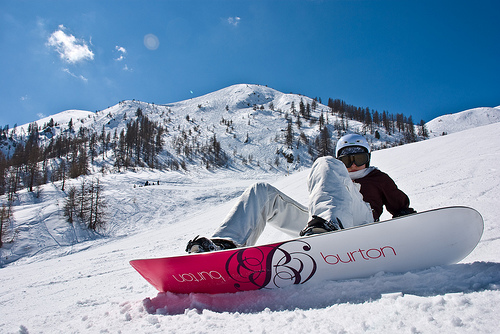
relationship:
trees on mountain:
[319, 97, 428, 140] [4, 78, 484, 242]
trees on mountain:
[100, 101, 170, 167] [4, 78, 484, 242]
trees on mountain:
[7, 126, 91, 183] [4, 78, 484, 242]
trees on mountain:
[55, 179, 108, 229] [4, 78, 484, 242]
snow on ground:
[17, 252, 118, 322] [9, 167, 498, 329]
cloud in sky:
[32, 20, 129, 92] [0, 3, 487, 138]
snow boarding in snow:
[128, 205, 486, 294] [0, 78, 500, 332]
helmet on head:
[333, 132, 372, 179] [339, 132, 372, 179]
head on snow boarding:
[339, 132, 372, 179] [128, 205, 486, 294]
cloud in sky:
[35, 24, 114, 82] [0, 3, 487, 138]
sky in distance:
[0, 3, 487, 138] [21, 12, 454, 125]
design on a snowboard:
[220, 249, 324, 286] [116, 167, 498, 325]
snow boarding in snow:
[128, 205, 486, 294] [0, 121, 499, 332]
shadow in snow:
[140, 259, 499, 317] [0, 121, 499, 332]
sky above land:
[0, 3, 487, 138] [45, 102, 303, 175]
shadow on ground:
[141, 261, 500, 315] [89, 285, 459, 331]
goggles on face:
[328, 147, 406, 187] [335, 146, 368, 174]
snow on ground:
[20, 219, 199, 312] [20, 200, 129, 304]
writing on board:
[300, 241, 420, 271] [130, 205, 488, 299]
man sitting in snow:
[184, 132, 422, 250] [37, 276, 91, 331]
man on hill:
[184, 132, 422, 250] [8, 132, 495, 328]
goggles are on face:
[338, 152, 369, 168] [333, 143, 368, 175]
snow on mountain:
[4, 258, 119, 332] [140, 70, 389, 160]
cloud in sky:
[42, 21, 112, 84] [13, 7, 498, 108]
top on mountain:
[209, 67, 278, 107] [5, 66, 399, 255]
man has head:
[184, 133, 417, 254] [335, 132, 371, 169]